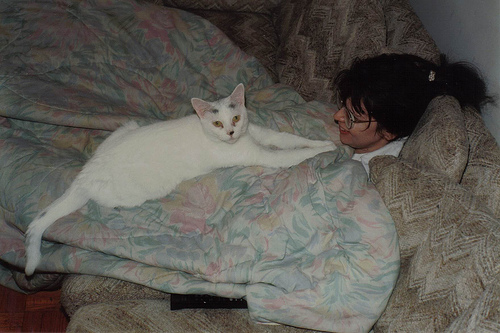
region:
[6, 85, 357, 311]
cat on top of comforter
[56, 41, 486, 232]
woman looks at cat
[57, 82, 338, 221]
white cat has black two black spots on the head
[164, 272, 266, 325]
remote control under the comforter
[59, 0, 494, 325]
chevron-patterned couch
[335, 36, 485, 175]
woman wears dark brown hair in ponytail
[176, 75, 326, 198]
cat has pink ears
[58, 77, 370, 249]
cat grips in front of woman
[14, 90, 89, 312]
cat's tail hangs slight off the comforter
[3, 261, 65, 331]
Parquet wood floors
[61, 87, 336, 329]
the cat is white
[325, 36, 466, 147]
woman's hair in pony tail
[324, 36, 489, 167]
woman's hair is black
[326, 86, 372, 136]
woman is wearing glasses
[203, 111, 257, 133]
cat's eyes are yellow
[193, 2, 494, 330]
the couch is brown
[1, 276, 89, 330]
floor is made of wood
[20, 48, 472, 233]
cat is laying on woman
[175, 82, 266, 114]
cat's ears are pink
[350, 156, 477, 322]
couch has zig zag designs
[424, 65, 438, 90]
Silver hair bling on woman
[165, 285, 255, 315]
Remote control under blanket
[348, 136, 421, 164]
White shirt of woman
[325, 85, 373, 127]
Glasses on woman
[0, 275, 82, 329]
Wood floor on bottom left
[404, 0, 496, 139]
White wall on top right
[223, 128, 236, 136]
Black spot on cats nose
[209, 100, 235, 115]
Two dark spots between cats ears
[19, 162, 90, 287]
White cats tail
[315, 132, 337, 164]
Two cats paws near woman's face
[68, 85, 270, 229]
the cat is white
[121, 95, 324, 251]
the cat is white